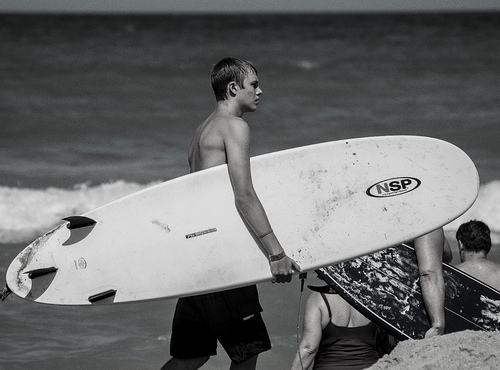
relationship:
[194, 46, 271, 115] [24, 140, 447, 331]
guy carrying surfboard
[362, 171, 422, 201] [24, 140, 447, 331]
logo on surfboard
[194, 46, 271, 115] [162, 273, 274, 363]
guy wearing shorts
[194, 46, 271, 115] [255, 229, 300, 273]
guy wearing bracelets